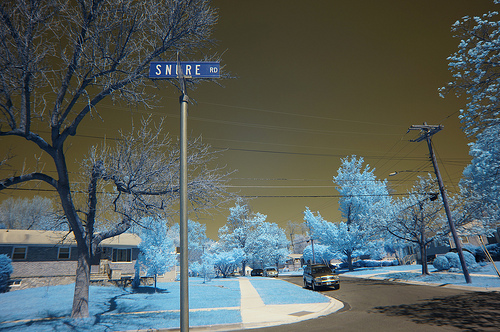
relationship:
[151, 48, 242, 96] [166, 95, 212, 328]
sign on pole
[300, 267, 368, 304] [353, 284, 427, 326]
suv on road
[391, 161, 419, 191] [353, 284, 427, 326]
street light for road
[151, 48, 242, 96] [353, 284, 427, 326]
sign for road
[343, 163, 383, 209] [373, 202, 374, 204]
tree with snow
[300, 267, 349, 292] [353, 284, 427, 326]
suv on road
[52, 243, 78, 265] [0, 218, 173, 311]
window on building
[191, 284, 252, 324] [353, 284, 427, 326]
grass with road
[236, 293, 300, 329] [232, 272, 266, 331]
corner of sidewalk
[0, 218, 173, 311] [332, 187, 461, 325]
building b park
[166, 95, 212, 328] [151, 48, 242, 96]
pole with sign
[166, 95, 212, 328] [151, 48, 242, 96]
pole for sign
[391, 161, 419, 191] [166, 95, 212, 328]
street light on pole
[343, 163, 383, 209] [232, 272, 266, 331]
tree near sidewalk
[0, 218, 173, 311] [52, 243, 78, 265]
building with window